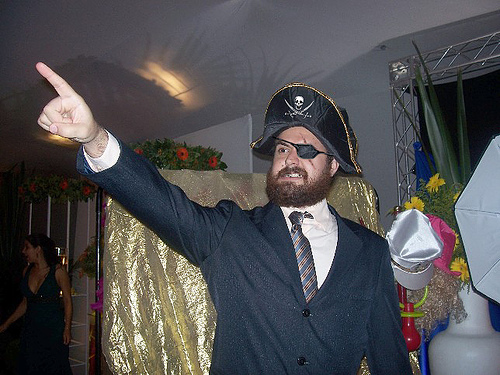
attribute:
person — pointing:
[33, 60, 414, 373]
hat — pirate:
[262, 77, 400, 159]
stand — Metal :
[382, 69, 430, 215]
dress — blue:
[20, 272, 61, 368]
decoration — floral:
[125, 135, 230, 170]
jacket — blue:
[73, 135, 416, 372]